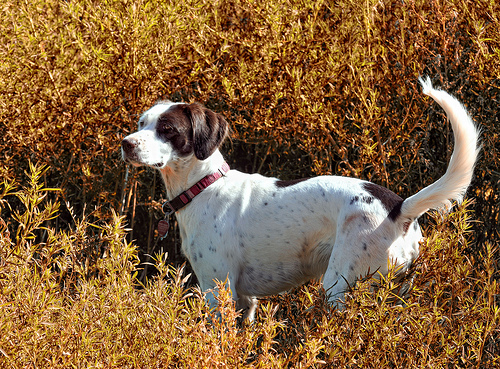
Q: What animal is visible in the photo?
A: Dog.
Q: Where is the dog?
A: In a grassy field.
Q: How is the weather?
A: Sunny.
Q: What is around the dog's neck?
A: A collar.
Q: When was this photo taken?
A: In the daytime.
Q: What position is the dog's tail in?
A: Pointing straight up.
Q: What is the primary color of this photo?
A: Yellow.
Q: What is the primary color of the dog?
A: White.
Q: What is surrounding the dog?
A: Plants.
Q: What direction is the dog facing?
A: Left.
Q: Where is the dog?
A: In a field.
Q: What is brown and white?
A: The dog.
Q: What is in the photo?
A: A dog.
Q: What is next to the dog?
A: Grass.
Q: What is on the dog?
A: Collar.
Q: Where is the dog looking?
A: To the left.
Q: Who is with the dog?
A: No people.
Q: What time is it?
A: Afternoon.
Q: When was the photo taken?
A: During the daytime.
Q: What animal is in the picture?
A: A dog.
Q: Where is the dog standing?
A: The grass.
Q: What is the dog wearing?
A: A red and brown collar.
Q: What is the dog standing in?
A: Tall bushes and grass.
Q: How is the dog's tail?
A: Raised up.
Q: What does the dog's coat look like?
A: White with brown spots.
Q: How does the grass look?
A: Brown and dried.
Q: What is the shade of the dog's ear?
A: Brown.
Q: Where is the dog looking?
A: To the left.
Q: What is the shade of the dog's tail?
A: White.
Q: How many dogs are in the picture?
A: One.